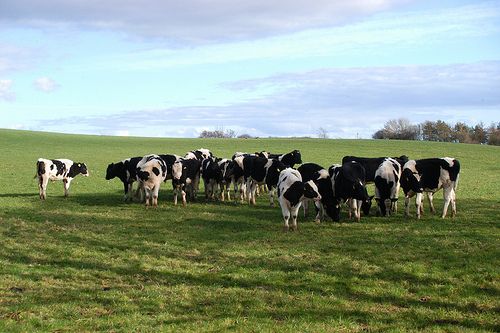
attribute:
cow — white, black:
[277, 168, 321, 228]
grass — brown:
[39, 271, 111, 293]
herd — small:
[29, 146, 462, 229]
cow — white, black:
[398, 153, 460, 216]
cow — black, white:
[275, 167, 317, 223]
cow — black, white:
[36, 157, 86, 198]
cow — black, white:
[173, 157, 201, 202]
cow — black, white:
[370, 157, 404, 222]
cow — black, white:
[32, 156, 90, 201]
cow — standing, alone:
[33, 146, 95, 196]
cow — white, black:
[403, 156, 461, 219]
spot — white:
[410, 171, 421, 183]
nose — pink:
[318, 194, 321, 200]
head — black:
[360, 194, 374, 217]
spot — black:
[49, 161, 55, 171]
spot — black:
[122, 156, 132, 169]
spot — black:
[151, 167, 160, 176]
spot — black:
[280, 176, 287, 181]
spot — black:
[390, 160, 401, 172]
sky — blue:
[2, 3, 498, 146]